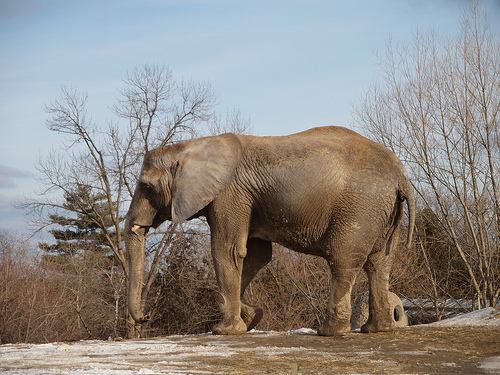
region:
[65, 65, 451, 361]
this is an elepjant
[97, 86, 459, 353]
the elephant is brown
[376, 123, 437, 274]
elephant has short tail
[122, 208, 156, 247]
tusk on the elephant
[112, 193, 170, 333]
trunk of the elephant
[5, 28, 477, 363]
a bright and clear day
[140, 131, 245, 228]
elephant has wide ears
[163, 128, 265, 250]
elephant has wide ears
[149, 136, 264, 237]
elephant has wide ears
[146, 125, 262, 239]
elephant has wide ears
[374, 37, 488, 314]
the tree is bare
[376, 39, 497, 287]
the tree is bare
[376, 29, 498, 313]
the tree is bare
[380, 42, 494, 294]
the tree is bare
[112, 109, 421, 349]
Large brown elephant on the grass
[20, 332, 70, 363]
Small patch of brown dirt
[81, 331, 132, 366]
Small patch of brown dirt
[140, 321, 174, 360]
Small patch of brown dirt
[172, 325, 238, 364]
Small patch of brown dirt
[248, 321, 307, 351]
Small patch of brown dirt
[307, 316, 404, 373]
Small patch of brown dirt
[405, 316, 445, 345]
Small patch of brown dirt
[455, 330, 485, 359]
Small patch of brown dirt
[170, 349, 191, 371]
Small patch of brown dirt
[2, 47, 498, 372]
a scene outside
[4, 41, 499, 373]
a scene during the day time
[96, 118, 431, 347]
an animal walking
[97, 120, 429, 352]
a gray elephant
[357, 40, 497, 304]
a tree with no leaves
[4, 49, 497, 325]
some trees in the background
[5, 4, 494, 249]
a sky with clouds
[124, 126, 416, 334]
an elephant is walking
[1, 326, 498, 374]
dirt on the ground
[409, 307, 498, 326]
a small little hill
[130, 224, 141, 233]
the tusk is short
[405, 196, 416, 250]
tail of an elephant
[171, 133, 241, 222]
ear of an elephant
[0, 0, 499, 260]
sparse clouds in sky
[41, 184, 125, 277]
leaves of tree are green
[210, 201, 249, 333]
leg of an elephant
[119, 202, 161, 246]
the elephant has tusks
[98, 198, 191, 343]
the trunk of the elepahntq